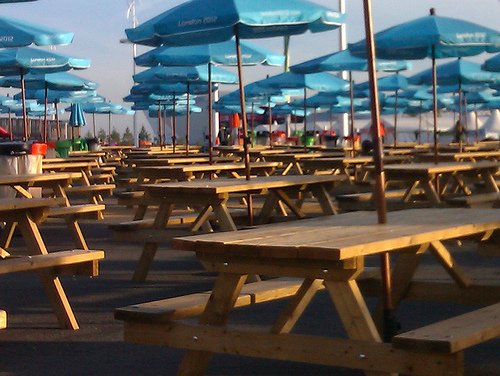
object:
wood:
[318, 280, 382, 346]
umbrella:
[130, 63, 240, 157]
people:
[214, 124, 231, 147]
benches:
[390, 305, 500, 359]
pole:
[234, 28, 253, 225]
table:
[0, 172, 91, 252]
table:
[0, 195, 82, 330]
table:
[361, 159, 499, 210]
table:
[130, 172, 347, 284]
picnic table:
[168, 209, 498, 375]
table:
[124, 161, 283, 211]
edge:
[114, 306, 177, 325]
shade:
[0, 335, 172, 374]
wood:
[177, 273, 259, 375]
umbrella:
[124, 1, 347, 227]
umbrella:
[0, 15, 75, 50]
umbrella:
[345, 5, 499, 198]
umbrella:
[131, 40, 286, 183]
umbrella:
[286, 44, 412, 179]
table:
[119, 157, 241, 209]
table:
[301, 155, 409, 194]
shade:
[0, 337, 360, 375]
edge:
[0, 251, 105, 275]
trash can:
[0, 142, 48, 229]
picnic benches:
[0, 248, 106, 275]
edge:
[168, 237, 340, 262]